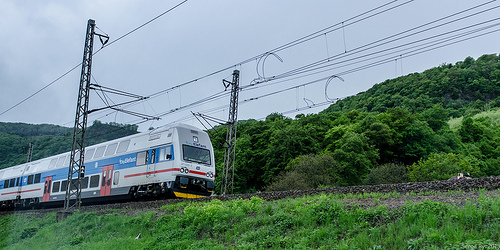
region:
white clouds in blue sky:
[9, 13, 44, 42]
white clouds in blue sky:
[22, 56, 76, 93]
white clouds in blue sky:
[18, 82, 63, 109]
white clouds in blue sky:
[113, 56, 155, 84]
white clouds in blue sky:
[158, 28, 199, 59]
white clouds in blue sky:
[228, 26, 257, 67]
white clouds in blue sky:
[300, 47, 371, 84]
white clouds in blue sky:
[23, 65, 125, 92]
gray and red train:
[15, 129, 213, 187]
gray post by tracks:
[78, 41, 100, 115]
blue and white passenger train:
[33, 136, 202, 236]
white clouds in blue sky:
[5, 49, 51, 79]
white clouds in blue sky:
[24, 70, 68, 118]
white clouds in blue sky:
[116, 19, 187, 67]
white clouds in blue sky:
[141, 47, 207, 116]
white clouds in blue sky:
[228, 29, 311, 64]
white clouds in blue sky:
[280, 29, 322, 87]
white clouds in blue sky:
[326, 36, 411, 68]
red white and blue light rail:
[10, 117, 208, 200]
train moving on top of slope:
[6, 113, 487, 243]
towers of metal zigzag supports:
[57, 15, 237, 210]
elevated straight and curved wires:
[35, 0, 490, 120]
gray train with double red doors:
[0, 122, 215, 202]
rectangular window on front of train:
[180, 135, 211, 165]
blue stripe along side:
[0, 140, 175, 187]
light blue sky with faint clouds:
[0, 0, 495, 130]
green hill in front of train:
[182, 51, 492, 202]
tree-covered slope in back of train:
[2, 115, 133, 166]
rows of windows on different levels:
[2, 135, 138, 198]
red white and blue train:
[27, 137, 217, 196]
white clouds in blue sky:
[2, 7, 66, 49]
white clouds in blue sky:
[7, 40, 73, 89]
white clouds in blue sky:
[9, 87, 67, 125]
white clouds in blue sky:
[110, 6, 178, 54]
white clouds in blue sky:
[120, 38, 155, 75]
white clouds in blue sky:
[202, 7, 268, 47]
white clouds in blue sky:
[250, 38, 311, 104]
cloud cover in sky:
[2, 0, 497, 127]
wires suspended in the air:
[8, 1, 497, 128]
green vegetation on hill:
[213, 54, 497, 189]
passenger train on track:
[3, 124, 215, 208]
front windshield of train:
[178, 142, 211, 167]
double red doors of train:
[99, 161, 115, 198]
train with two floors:
[2, 124, 177, 203]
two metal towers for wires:
[64, 19, 239, 208]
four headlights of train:
[177, 164, 214, 181]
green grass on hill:
[2, 188, 498, 248]